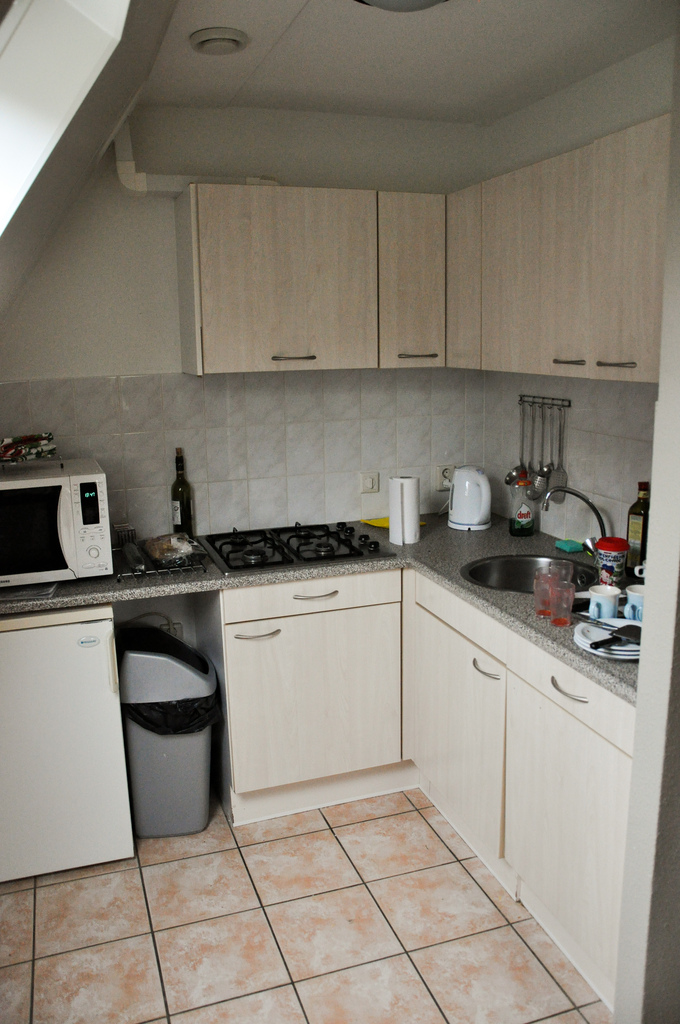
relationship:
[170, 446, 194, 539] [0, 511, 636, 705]
bottle on counter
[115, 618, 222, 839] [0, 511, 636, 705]
trash can beneath counter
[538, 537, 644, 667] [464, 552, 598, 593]
dishes beside sink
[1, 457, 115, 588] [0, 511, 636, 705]
microwave on counter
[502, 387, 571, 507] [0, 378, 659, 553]
utinsils on backsplash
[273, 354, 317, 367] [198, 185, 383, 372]
handle on cabinet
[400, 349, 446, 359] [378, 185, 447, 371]
handle on cabinet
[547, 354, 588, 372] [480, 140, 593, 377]
handle on cabinet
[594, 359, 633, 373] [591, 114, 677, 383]
handle on cabinet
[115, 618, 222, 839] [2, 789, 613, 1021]
trash can on floor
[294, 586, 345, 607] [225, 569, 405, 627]
handle on drawer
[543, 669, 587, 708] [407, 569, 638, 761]
handle on drawer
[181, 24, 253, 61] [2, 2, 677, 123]
smoke detector on ceiling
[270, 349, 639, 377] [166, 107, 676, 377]
handles on cabinets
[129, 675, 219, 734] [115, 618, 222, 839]
bag in trash can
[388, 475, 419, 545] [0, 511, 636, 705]
paper towels are on counter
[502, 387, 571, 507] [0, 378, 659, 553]
utinsils are on backsplash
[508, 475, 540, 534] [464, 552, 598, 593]
dish soap near sink